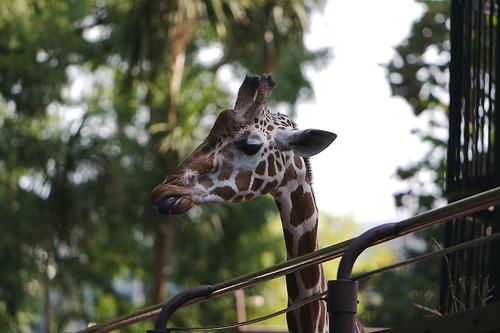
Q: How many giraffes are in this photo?
A: One.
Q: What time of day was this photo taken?
A: Daytime.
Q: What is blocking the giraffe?
A: A fence.